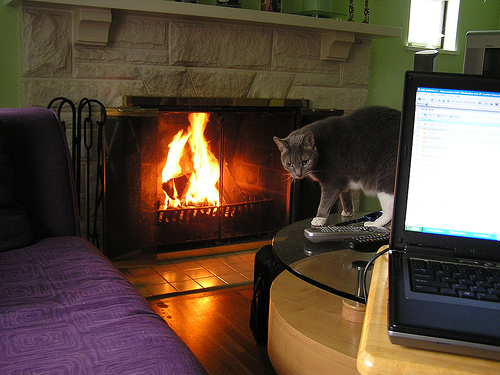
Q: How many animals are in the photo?
A: One.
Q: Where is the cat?
A: Table.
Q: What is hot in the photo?
A: Fire.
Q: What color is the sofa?
A: Blue.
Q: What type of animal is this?
A: Cat.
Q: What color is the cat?
A: Grey.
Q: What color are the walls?
A: Green.